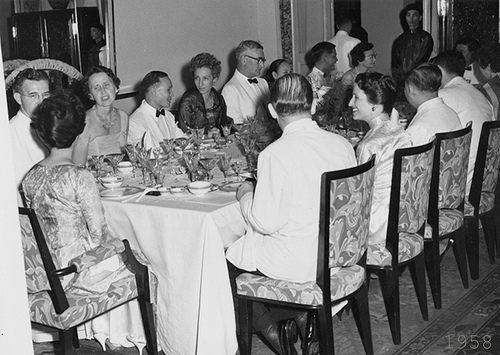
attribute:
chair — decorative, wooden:
[326, 168, 370, 262]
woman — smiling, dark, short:
[345, 77, 401, 240]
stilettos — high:
[323, 305, 356, 328]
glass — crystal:
[187, 146, 231, 180]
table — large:
[179, 203, 230, 234]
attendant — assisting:
[376, 2, 450, 77]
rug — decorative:
[435, 314, 483, 346]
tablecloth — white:
[141, 223, 196, 252]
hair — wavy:
[362, 78, 401, 113]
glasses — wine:
[241, 54, 265, 63]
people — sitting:
[21, 41, 436, 227]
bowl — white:
[152, 161, 214, 196]